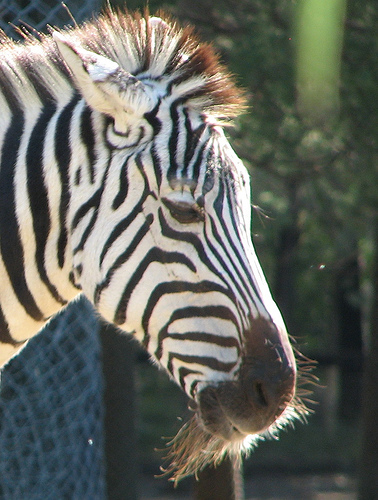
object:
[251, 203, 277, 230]
eyelashes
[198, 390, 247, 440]
chin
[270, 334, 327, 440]
hairs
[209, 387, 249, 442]
mouth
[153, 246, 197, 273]
black stripe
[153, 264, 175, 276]
white stripe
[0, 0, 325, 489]
animal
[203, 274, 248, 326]
sign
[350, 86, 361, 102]
ground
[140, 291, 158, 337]
stripes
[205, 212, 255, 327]
stripe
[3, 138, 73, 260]
fur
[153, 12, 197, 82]
fur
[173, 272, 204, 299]
stripes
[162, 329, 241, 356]
stripe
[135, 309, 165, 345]
fur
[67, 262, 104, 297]
stripes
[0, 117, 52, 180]
stripes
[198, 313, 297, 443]
muzzle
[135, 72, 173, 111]
stripes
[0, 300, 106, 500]
fence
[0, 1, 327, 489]
zebra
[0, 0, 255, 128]
mane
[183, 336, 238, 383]
stripes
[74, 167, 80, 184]
stripe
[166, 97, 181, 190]
stripe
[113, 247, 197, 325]
stripe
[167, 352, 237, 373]
stripe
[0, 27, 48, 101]
fur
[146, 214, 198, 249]
stripes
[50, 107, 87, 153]
stripes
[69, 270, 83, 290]
stripe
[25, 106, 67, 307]
stripe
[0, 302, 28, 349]
stripe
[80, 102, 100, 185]
stripe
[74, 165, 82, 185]
stripe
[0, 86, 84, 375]
neck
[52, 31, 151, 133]
ear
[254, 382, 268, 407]
nostril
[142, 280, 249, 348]
stripe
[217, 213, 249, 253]
stripes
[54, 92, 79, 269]
stripe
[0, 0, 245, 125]
black/white fur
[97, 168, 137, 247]
stripe fur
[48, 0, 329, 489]
zebra head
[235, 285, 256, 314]
stripes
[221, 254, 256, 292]
stripes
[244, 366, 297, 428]
nose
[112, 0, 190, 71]
fur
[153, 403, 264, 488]
hair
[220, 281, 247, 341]
stripes